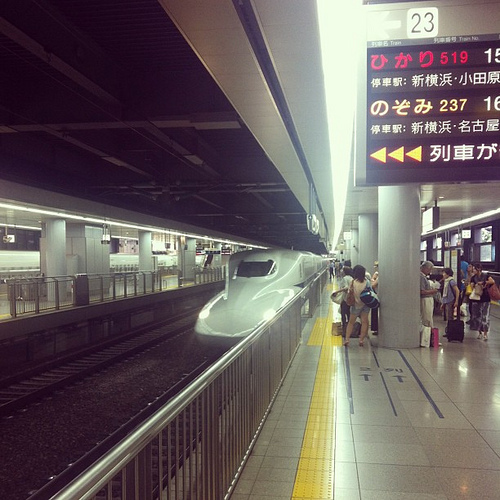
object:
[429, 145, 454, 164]
letter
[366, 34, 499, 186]
sign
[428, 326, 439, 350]
bag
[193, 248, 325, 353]
train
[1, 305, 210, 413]
tracks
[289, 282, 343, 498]
line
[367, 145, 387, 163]
arrow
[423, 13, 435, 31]
number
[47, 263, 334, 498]
railing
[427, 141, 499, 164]
writing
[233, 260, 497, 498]
platform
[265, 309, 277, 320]
headlight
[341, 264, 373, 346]
person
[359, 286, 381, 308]
luggage